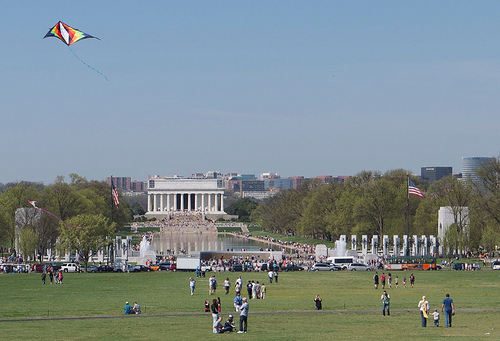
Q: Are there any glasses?
A: No, there are no glasses.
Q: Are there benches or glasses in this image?
A: No, there are no glasses or benches.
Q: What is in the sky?
A: The clouds are in the sky.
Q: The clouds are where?
A: The clouds are in the sky.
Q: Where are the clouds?
A: The clouds are in the sky.